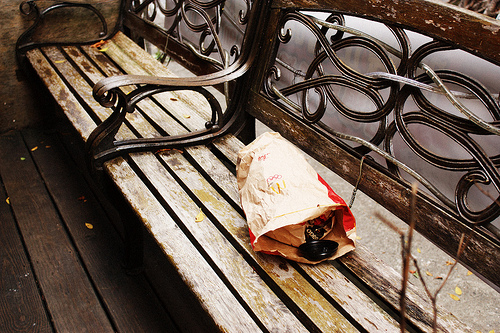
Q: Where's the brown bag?
A: On the bench.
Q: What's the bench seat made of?
A: Wood.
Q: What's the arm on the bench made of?
A: Metal.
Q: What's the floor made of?
A: Wood.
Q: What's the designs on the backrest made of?
A: Metal.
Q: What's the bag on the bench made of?
A: Paper.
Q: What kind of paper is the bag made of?
A: Brown paper.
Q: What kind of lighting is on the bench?
A: Rope lighting.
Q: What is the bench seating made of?
A: Wood slats.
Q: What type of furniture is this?
A: Bench.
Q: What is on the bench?
A: A bag.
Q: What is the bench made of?
A: Wood.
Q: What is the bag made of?
A: Paper.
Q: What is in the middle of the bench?
A: Armrest.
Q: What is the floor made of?
A: Wood.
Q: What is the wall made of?
A: Stone.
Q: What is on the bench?
A: Stick.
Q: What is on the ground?
A: Leaves.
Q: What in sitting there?
A: Bag on bench.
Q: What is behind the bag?
A: Metal bench.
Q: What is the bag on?
A: Bench.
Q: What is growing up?
A: Sticks in bench.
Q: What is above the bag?
A: Metal design.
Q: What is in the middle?
A: Brass handle.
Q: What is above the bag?
A: Decorative back.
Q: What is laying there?
A: Paper bag.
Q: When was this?
A: Daytime.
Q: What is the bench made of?
A: Wood.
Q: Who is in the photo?
A: No one.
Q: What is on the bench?
A: Package.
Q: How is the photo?
A: Clear.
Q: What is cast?
A: Shadow.